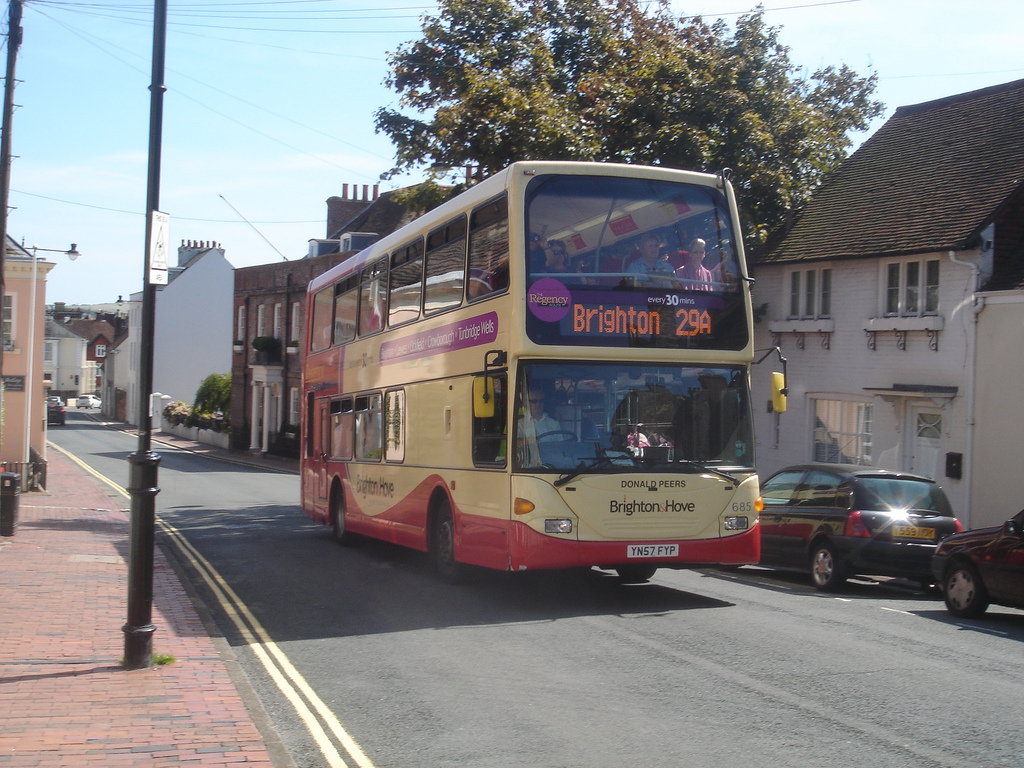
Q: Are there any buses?
A: Yes, there is a bus.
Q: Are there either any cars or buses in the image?
A: Yes, there is a bus.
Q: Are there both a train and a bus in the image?
A: No, there is a bus but no trains.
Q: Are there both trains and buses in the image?
A: No, there is a bus but no trains.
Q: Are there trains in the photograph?
A: No, there are no trains.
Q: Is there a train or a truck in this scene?
A: No, there are no trains or trucks.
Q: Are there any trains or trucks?
A: No, there are no trains or trucks.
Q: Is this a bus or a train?
A: This is a bus.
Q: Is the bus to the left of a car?
A: Yes, the bus is to the left of a car.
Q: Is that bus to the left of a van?
A: No, the bus is to the left of a car.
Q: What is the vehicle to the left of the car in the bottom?
A: The vehicle is a bus.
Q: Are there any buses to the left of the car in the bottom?
A: Yes, there is a bus to the left of the car.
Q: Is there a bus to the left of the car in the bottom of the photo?
A: Yes, there is a bus to the left of the car.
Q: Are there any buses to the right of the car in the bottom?
A: No, the bus is to the left of the car.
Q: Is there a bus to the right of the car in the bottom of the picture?
A: No, the bus is to the left of the car.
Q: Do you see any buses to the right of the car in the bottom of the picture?
A: No, the bus is to the left of the car.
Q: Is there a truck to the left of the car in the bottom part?
A: No, there is a bus to the left of the car.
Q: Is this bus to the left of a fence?
A: No, the bus is to the left of the car.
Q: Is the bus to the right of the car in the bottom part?
A: No, the bus is to the left of the car.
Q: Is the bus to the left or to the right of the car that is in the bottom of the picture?
A: The bus is to the left of the car.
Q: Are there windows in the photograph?
A: Yes, there is a window.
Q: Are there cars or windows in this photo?
A: Yes, there is a window.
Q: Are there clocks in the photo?
A: No, there are no clocks.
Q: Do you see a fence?
A: No, there are no fences.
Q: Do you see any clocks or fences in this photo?
A: No, there are no fences or clocks.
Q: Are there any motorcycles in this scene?
A: No, there are no motorcycles.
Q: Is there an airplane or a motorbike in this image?
A: No, there are no motorcycles or airplanes.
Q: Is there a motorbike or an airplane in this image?
A: No, there are no motorcycles or airplanes.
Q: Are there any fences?
A: No, there are no fences.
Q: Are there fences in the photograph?
A: No, there are no fences.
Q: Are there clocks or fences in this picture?
A: No, there are no fences or clocks.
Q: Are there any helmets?
A: No, there are no helmets.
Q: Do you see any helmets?
A: No, there are no helmets.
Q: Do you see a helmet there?
A: No, there are no helmets.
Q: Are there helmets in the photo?
A: No, there are no helmets.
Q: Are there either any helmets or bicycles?
A: No, there are no helmets or bicycles.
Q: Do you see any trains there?
A: No, there are no trains.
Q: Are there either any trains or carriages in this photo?
A: No, there are no trains or carriages.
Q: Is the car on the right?
A: Yes, the car is on the right of the image.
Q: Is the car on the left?
A: No, the car is on the right of the image.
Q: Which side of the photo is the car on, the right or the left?
A: The car is on the right of the image.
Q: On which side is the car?
A: The car is on the right of the image.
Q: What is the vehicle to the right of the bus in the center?
A: The vehicle is a car.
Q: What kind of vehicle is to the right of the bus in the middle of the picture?
A: The vehicle is a car.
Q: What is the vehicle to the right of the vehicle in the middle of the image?
A: The vehicle is a car.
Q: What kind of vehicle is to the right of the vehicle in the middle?
A: The vehicle is a car.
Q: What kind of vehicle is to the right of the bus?
A: The vehicle is a car.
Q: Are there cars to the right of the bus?
A: Yes, there is a car to the right of the bus.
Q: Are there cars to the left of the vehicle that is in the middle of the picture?
A: No, the car is to the right of the bus.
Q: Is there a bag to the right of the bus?
A: No, there is a car to the right of the bus.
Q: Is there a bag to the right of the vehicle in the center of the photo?
A: No, there is a car to the right of the bus.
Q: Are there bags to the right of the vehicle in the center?
A: No, there is a car to the right of the bus.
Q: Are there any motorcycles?
A: No, there are no motorcycles.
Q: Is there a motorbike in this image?
A: No, there are no motorcycles.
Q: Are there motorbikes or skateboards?
A: No, there are no motorbikes or skateboards.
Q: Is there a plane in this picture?
A: No, there are no airplanes.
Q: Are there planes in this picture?
A: No, there are no planes.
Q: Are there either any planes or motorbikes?
A: No, there are no planes or motorbikes.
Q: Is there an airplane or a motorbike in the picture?
A: No, there are no airplanes or motorcycles.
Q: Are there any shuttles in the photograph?
A: No, there are no shuttles.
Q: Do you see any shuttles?
A: No, there are no shuttles.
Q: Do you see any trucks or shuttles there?
A: No, there are no shuttles or trucks.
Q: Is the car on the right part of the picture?
A: Yes, the car is on the right of the image.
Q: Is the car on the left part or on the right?
A: The car is on the right of the image.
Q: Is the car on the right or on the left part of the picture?
A: The car is on the right of the image.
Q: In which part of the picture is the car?
A: The car is on the right of the image.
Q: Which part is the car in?
A: The car is on the right of the image.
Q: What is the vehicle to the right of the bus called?
A: The vehicle is a car.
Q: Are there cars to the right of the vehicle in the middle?
A: Yes, there is a car to the right of the bus.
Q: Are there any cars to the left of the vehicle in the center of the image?
A: No, the car is to the right of the bus.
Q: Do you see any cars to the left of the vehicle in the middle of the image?
A: No, the car is to the right of the bus.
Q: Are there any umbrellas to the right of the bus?
A: No, there is a car to the right of the bus.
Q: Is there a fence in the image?
A: No, there are no fences.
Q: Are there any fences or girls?
A: No, there are no fences or girls.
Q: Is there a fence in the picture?
A: No, there are no fences.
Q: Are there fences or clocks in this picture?
A: No, there are no fences or clocks.